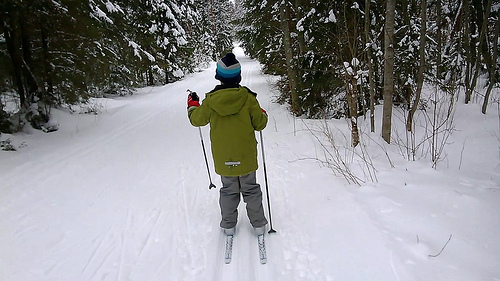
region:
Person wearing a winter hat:
[201, 43, 258, 94]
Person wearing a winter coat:
[180, 39, 287, 190]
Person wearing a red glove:
[174, 80, 216, 127]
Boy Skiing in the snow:
[177, 42, 290, 274]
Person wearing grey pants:
[185, 46, 297, 276]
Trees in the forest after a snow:
[46, 21, 181, 188]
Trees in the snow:
[312, 12, 438, 198]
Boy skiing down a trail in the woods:
[166, 17, 318, 278]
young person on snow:
[181, 50, 272, 265]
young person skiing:
[185, 45, 275, 265]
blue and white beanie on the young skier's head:
[212, 50, 243, 83]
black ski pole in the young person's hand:
[183, 87, 215, 188]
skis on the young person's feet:
[216, 215, 271, 261]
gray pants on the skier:
[216, 175, 268, 228]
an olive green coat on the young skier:
[186, 82, 266, 174]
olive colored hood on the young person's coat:
[205, 82, 250, 112]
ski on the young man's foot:
[220, 225, 236, 265]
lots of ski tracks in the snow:
[0, 82, 182, 279]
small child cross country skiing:
[168, 43, 303, 270]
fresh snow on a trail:
[91, 128, 176, 263]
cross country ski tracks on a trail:
[212, 257, 278, 279]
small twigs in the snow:
[301, 104, 469, 186]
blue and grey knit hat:
[211, 52, 247, 84]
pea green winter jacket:
[185, 85, 270, 179]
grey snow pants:
[217, 171, 268, 238]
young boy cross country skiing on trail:
[170, 36, 302, 263]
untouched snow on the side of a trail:
[411, 165, 481, 257]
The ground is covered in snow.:
[1, 25, 498, 278]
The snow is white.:
[0, 33, 499, 279]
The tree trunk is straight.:
[376, 0, 401, 145]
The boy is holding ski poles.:
[169, 45, 289, 270]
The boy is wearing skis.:
[185, 50, 285, 272]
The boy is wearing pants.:
[181, 45, 283, 272]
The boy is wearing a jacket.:
[179, 47, 285, 268]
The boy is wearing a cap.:
[182, 48, 289, 273]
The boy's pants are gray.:
[180, 47, 282, 274]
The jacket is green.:
[181, 53, 270, 179]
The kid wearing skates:
[187, 49, 281, 266]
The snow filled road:
[0, 1, 498, 279]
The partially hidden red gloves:
[259, 102, 269, 117]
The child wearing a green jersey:
[185, 53, 277, 263]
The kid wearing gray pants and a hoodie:
[186, 51, 276, 263]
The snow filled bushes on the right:
[236, 1, 496, 186]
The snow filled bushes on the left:
[0, 1, 236, 151]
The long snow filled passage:
[0, 41, 470, 278]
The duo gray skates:
[220, 225, 270, 265]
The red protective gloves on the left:
[184, 89, 200, 111]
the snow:
[318, 210, 374, 232]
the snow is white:
[286, 206, 353, 258]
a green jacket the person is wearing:
[208, 90, 258, 177]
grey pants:
[218, 180, 270, 233]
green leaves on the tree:
[350, 57, 360, 82]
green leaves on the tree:
[308, 26, 346, 86]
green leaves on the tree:
[136, 35, 186, 75]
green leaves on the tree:
[72, 43, 116, 92]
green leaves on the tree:
[457, 5, 489, 95]